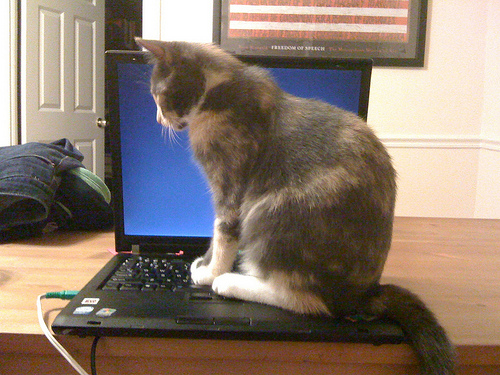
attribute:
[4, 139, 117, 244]
jeans — blue, crumpled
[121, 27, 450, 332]
cat — brown, orange, adult, multicolored, white, gray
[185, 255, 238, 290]
paws — white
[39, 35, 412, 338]
computer — black, connected, small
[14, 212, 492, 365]
table — wooden, wood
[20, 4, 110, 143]
door — wood, white, open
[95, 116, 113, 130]
knob — silver, small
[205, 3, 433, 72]
poster — red, white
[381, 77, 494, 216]
walls — white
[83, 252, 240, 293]
keyboard — black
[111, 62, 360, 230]
screen — blue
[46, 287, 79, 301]
cord — green, white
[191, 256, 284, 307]
feet — white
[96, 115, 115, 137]
doorknob — shiny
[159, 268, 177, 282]
letters — white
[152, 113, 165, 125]
nose — pink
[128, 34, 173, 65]
ear — pointy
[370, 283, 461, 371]
tail — gray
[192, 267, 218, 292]
paw — white